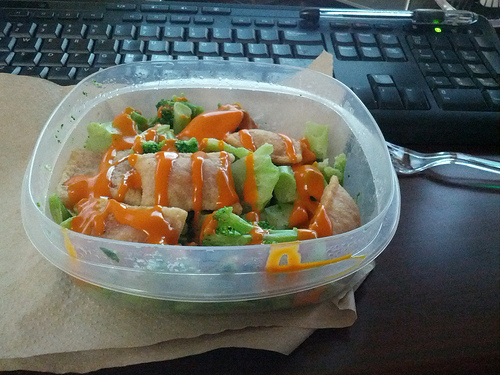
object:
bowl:
[20, 56, 404, 318]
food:
[53, 94, 363, 315]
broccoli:
[198, 204, 300, 262]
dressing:
[68, 107, 341, 237]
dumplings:
[307, 174, 360, 247]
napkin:
[1, 41, 375, 375]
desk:
[0, 141, 498, 374]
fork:
[375, 132, 500, 177]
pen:
[300, 6, 446, 21]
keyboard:
[2, 1, 499, 146]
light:
[433, 26, 443, 34]